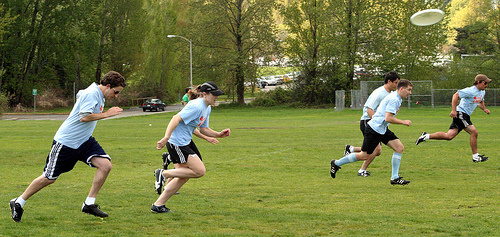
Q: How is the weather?
A: It is sunny.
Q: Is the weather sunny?
A: Yes, it is sunny.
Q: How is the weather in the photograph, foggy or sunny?
A: It is sunny.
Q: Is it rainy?
A: No, it is sunny.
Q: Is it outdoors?
A: Yes, it is outdoors.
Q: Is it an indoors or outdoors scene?
A: It is outdoors.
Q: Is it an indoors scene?
A: No, it is outdoors.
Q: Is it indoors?
A: No, it is outdoors.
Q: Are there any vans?
A: No, there are no vans.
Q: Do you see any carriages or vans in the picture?
A: No, there are no vans or carriages.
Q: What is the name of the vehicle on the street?
A: The vehicle is a car.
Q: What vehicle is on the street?
A: The vehicle is a car.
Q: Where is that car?
A: The car is on the street.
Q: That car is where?
A: The car is on the street.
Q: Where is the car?
A: The car is on the street.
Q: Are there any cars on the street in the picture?
A: Yes, there is a car on the street.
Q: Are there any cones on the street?
A: No, there is a car on the street.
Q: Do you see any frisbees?
A: Yes, there is a frisbee.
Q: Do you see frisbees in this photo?
A: Yes, there is a frisbee.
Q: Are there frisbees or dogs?
A: Yes, there is a frisbee.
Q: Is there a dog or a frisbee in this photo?
A: Yes, there is a frisbee.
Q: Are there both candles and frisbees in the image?
A: No, there is a frisbee but no candles.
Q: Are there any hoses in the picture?
A: No, there are no hoses.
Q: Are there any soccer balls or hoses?
A: No, there are no hoses or soccer balls.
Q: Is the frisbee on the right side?
A: Yes, the frisbee is on the right of the image.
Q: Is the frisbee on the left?
A: No, the frisbee is on the right of the image.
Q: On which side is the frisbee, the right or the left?
A: The frisbee is on the right of the image.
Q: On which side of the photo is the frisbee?
A: The frisbee is on the right of the image.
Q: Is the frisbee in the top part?
A: Yes, the frisbee is in the top of the image.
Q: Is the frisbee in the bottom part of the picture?
A: No, the frisbee is in the top of the image.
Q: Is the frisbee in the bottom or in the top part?
A: The frisbee is in the top of the image.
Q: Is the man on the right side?
A: Yes, the man is on the right of the image.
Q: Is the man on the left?
A: No, the man is on the right of the image.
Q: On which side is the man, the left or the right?
A: The man is on the right of the image.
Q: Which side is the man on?
A: The man is on the right of the image.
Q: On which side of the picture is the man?
A: The man is on the right of the image.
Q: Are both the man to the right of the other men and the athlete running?
A: Yes, both the man and the athlete are running.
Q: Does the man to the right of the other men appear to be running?
A: Yes, the man is running.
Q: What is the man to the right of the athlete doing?
A: The man is running.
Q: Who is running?
A: The man is running.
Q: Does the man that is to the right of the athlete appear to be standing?
A: No, the man is running.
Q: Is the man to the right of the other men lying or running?
A: The man is running.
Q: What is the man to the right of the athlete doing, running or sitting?
A: The man is running.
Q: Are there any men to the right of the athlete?
A: Yes, there is a man to the right of the athlete.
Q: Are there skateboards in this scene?
A: No, there are no skateboards.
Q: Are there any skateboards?
A: No, there are no skateboards.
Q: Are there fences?
A: Yes, there is a fence.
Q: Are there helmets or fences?
A: Yes, there is a fence.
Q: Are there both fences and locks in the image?
A: No, there is a fence but no locks.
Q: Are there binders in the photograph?
A: No, there are no binders.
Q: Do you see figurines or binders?
A: No, there are no binders or figurines.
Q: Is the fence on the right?
A: Yes, the fence is on the right of the image.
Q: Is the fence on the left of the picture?
A: No, the fence is on the right of the image.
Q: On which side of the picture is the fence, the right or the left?
A: The fence is on the right of the image.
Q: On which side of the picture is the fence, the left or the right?
A: The fence is on the right of the image.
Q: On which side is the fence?
A: The fence is on the right of the image.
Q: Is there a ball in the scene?
A: No, there are no balls.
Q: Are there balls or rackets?
A: No, there are no balls or rackets.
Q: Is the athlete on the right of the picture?
A: Yes, the athlete is on the right of the image.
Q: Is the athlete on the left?
A: No, the athlete is on the right of the image.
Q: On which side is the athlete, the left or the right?
A: The athlete is on the right of the image.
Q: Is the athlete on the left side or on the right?
A: The athlete is on the right of the image.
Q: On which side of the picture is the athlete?
A: The athlete is on the right of the image.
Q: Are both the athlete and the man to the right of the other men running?
A: Yes, both the athlete and the man are running.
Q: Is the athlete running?
A: Yes, the athlete is running.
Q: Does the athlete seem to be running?
A: Yes, the athlete is running.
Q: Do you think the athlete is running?
A: Yes, the athlete is running.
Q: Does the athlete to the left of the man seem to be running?
A: Yes, the athlete is running.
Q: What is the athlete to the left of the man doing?
A: The athlete is running.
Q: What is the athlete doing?
A: The athlete is running.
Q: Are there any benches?
A: No, there are no benches.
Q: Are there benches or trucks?
A: No, there are no benches or trucks.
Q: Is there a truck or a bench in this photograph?
A: No, there are no benches or trucks.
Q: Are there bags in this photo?
A: No, there are no bags.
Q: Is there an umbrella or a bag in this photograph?
A: No, there are no bags or umbrellas.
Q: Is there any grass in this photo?
A: Yes, there is grass.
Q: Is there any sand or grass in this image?
A: Yes, there is grass.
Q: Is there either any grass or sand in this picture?
A: Yes, there is grass.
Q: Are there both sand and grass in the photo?
A: No, there is grass but no sand.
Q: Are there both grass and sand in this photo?
A: No, there is grass but no sand.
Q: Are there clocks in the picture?
A: No, there are no clocks.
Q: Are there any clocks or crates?
A: No, there are no clocks or crates.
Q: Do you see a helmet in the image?
A: No, there are no helmets.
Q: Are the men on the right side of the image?
A: Yes, the men are on the right of the image.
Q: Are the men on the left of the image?
A: No, the men are on the right of the image.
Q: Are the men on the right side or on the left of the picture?
A: The men are on the right of the image.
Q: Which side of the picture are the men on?
A: The men are on the right of the image.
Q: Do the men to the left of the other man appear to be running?
A: Yes, the men are running.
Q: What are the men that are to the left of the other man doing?
A: The men are running.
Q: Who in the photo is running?
A: The men are running.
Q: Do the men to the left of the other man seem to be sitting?
A: No, the men are running.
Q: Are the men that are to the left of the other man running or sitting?
A: The men are running.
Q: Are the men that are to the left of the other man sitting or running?
A: The men are running.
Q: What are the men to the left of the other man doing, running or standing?
A: The men are running.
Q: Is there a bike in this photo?
A: No, there are no bikes.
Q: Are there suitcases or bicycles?
A: No, there are no bicycles or suitcases.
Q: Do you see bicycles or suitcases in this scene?
A: No, there are no bicycles or suitcases.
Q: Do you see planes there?
A: No, there are no planes.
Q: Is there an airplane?
A: No, there are no airplanes.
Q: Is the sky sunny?
A: Yes, the sky is sunny.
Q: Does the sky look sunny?
A: Yes, the sky is sunny.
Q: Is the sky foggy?
A: No, the sky is sunny.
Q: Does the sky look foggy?
A: No, the sky is sunny.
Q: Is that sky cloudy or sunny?
A: The sky is sunny.